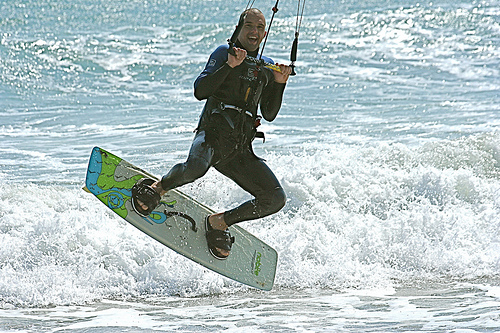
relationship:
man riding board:
[135, 7, 293, 258] [81, 139, 283, 290]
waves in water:
[3, 138, 491, 301] [3, 4, 498, 329]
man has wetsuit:
[135, 7, 293, 258] [160, 44, 289, 224]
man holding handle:
[135, 7, 293, 258] [224, 16, 303, 76]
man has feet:
[135, 7, 293, 258] [128, 177, 239, 260]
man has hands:
[135, 7, 293, 258] [220, 41, 296, 82]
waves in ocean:
[3, 138, 491, 301] [3, 4, 498, 329]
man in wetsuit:
[135, 7, 293, 258] [160, 44, 289, 224]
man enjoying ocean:
[135, 7, 293, 258] [3, 4, 498, 329]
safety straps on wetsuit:
[213, 80, 264, 153] [160, 44, 289, 224]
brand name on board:
[247, 245, 266, 283] [81, 139, 283, 290]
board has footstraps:
[81, 139, 283, 290] [130, 178, 241, 259]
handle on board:
[167, 204, 197, 233] [81, 139, 283, 290]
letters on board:
[247, 245, 266, 283] [81, 139, 283, 290]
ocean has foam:
[3, 4, 498, 329] [35, 6, 490, 87]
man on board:
[135, 7, 293, 258] [81, 139, 283, 290]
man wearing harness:
[135, 7, 293, 258] [213, 80, 264, 153]